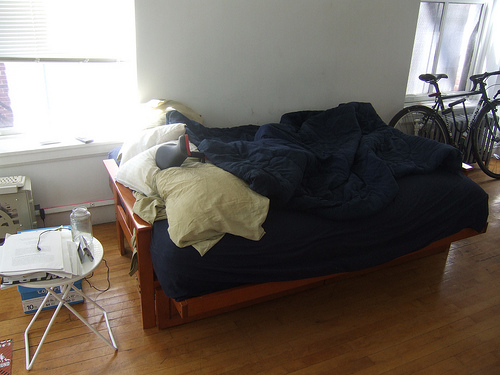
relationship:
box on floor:
[19, 277, 86, 311] [0, 159, 498, 374]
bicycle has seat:
[388, 70, 499, 180] [412, 63, 458, 88]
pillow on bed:
[153, 156, 269, 257] [100, 80, 499, 280]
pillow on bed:
[153, 156, 270, 250] [234, 122, 484, 254]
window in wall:
[0, 0, 133, 135] [170, 9, 361, 129]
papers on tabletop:
[3, 223, 84, 278] [0, 222, 102, 287]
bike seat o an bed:
[152, 134, 205, 172] [103, 98, 488, 329]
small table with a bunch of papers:
[1, 224, 121, 371] [2, 228, 87, 282]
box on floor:
[15, 225, 85, 315] [109, 318, 227, 373]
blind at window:
[0, 0, 137, 67] [2, 3, 137, 150]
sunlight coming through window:
[67, 171, 136, 375] [16, 4, 150, 141]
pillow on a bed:
[153, 156, 270, 250] [96, 123, 497, 310]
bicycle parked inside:
[388, 70, 499, 180] [390, 74, 499, 216]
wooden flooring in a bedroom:
[367, 324, 419, 370] [12, 8, 490, 365]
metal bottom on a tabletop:
[14, 302, 131, 353] [0, 227, 104, 288]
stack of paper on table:
[15, 228, 68, 346] [3, 222, 118, 337]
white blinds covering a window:
[6, 10, 117, 67] [378, 0, 469, 97]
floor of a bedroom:
[0, 159, 498, 374] [0, 189, 445, 375]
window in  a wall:
[0, 0, 133, 135] [225, 50, 324, 118]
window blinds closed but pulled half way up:
[0, 2, 132, 130] [55, 66, 117, 168]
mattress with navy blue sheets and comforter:
[109, 130, 490, 272] [112, 112, 270, 249]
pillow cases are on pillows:
[115, 122, 201, 202] [111, 104, 261, 240]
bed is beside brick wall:
[103, 98, 488, 329] [170, 35, 351, 88]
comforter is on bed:
[111, 100, 491, 300] [103, 98, 488, 329]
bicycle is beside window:
[388, 70, 499, 180] [398, 0, 491, 102]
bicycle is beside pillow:
[402, 64, 498, 180] [73, 72, 287, 275]